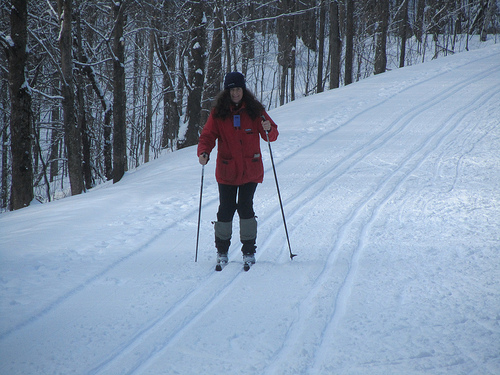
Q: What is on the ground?
A: Snow.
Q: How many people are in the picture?
A: One.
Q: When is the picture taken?
A: Winter.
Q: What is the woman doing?
A: Cross country skiing.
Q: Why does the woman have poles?
A: Leverage.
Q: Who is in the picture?
A: A woman.